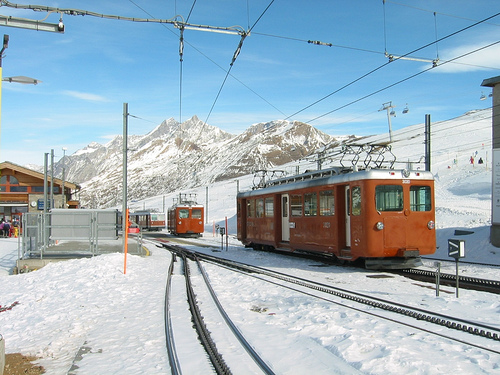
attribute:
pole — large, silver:
[117, 102, 135, 282]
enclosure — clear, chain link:
[12, 203, 129, 265]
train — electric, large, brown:
[232, 162, 456, 278]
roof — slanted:
[0, 163, 81, 197]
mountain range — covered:
[49, 109, 391, 226]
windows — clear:
[0, 180, 58, 194]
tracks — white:
[4, 234, 499, 375]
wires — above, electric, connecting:
[22, 6, 500, 140]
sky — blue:
[9, 2, 495, 164]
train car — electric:
[170, 167, 437, 268]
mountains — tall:
[84, 114, 340, 180]